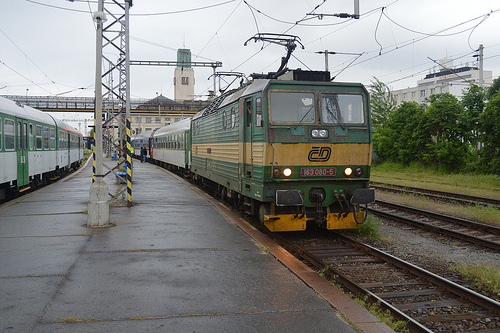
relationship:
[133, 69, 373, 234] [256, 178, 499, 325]
train over railroad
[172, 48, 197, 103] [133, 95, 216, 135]
tower over building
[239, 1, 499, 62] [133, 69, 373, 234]
wires above train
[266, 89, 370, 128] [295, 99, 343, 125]
windshield has wipers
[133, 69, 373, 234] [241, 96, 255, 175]
train has door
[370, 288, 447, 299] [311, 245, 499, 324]
tie in railroad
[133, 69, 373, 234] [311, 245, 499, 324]
train on railroad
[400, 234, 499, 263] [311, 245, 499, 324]
gravel between railroad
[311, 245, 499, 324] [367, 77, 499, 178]
railroad beside trees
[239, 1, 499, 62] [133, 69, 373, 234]
wires over train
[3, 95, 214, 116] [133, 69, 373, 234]
bridge over train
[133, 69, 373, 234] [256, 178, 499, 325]
train on railroad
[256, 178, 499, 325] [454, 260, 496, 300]
railroad has grass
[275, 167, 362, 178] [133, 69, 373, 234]
headlights on train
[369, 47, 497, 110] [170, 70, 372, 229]
building on right side of train